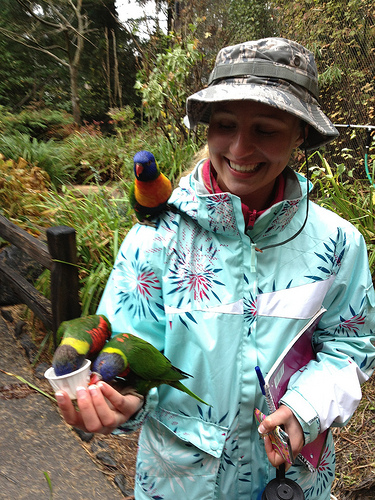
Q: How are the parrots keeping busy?
A: Eating.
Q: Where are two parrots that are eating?
A: Woman's right hand.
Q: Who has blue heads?
A: All three parrots.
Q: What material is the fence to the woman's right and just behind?
A: Wood.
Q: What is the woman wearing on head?
A: Frumpy hat.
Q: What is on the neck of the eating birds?
A: Yellow stripe.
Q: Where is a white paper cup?
A: Right hand of woman.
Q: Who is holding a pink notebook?
A: Lady with the birds.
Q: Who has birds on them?
A: The lady.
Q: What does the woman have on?
A: Rain coat.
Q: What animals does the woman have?
A: Parrots.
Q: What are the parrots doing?
A: Eating.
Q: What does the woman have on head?
A: Hat.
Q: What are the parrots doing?
A: Eating.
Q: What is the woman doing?
A: Smiling.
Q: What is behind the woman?
A: Trees.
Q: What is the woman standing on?
A: Pathway.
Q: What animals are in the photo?
A: Birds.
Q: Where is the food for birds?
A: In hand.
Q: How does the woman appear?
A: Happy.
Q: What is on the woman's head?
A: Hat.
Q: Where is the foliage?
A: Behind woman.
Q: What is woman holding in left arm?
A: Notebook.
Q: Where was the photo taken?
A: Bird sanctuary.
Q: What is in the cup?
A: Food.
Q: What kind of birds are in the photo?
A: Parakeets.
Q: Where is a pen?
A: Notebook spiral.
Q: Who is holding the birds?
A: The woman.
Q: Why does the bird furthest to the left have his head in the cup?
A: To eat.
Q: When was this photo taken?
A: Daytime.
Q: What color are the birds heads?
A: Blue.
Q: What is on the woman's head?
A: Hat.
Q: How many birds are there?
A: Three.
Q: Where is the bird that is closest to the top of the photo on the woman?
A: Shoulder.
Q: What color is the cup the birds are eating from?
A: White.